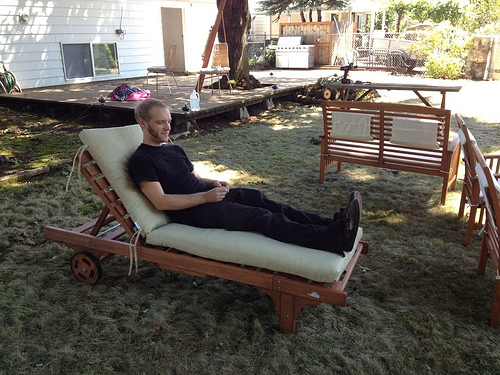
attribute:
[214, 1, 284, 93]
tree trunk — large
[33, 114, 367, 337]
chaise lounge — wood, in use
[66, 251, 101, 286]
wheel — back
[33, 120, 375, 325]
lawn chair — wooden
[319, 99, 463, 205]
bench — wooden, empty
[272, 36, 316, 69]
grill — bbq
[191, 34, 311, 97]
tree — large, brown, trunk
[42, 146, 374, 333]
chair — brown, wooden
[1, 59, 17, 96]
hose — green, garden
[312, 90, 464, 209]
bench — brown, wooden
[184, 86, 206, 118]
bottle — plastic, filled with clear liquid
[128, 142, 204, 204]
shirt — black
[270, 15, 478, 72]
fence — chain link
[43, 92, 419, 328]
chair — wooden, reclining, lawn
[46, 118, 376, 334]
lounge —  chaise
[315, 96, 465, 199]
bench — unoccupied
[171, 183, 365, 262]
pants — black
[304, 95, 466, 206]
bench — empty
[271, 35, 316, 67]
grill — barbecue, outdoor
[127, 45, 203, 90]
chair — brown, white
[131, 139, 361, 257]
clothing — black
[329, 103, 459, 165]
cushions — white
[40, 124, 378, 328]
chair — tan